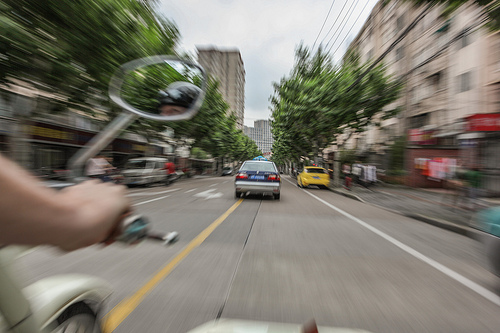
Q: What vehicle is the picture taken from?
A: Motorcycle.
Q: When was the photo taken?
A: During the daytime.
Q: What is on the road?
A: Cars.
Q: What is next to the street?
A: Buildings.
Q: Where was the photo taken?
A: On a bike.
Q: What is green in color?
A: The trees.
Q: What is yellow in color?
A: The line.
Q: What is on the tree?
A: Leaves.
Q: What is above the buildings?
A: The sky.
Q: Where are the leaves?
A: On the trees.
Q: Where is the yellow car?
A: On the street.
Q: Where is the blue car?
A: On the street.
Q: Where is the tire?
A: On the car.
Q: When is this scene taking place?
A: Daytime.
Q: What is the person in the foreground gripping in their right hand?
A: Handle.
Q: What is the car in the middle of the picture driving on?
A: Street.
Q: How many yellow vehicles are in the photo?
A: One.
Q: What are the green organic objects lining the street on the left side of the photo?
A: Trees.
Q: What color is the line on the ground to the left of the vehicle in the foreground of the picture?
A: Yellow.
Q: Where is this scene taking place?
A: On a city street.